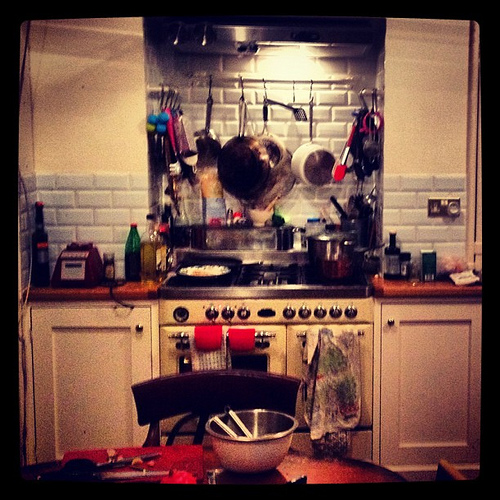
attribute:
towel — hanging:
[275, 344, 370, 421]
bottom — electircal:
[50, 242, 106, 284]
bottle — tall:
[32, 199, 50, 286]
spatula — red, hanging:
[334, 121, 351, 181]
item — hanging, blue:
[149, 100, 158, 121]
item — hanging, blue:
[156, 108, 168, 121]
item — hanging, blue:
[155, 126, 167, 136]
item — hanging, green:
[147, 127, 157, 139]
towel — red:
[229, 326, 254, 352]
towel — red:
[189, 325, 222, 350]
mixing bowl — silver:
[206, 408, 298, 471]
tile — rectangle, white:
[59, 171, 96, 189]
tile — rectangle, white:
[96, 174, 128, 187]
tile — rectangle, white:
[38, 190, 78, 207]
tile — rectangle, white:
[74, 189, 114, 206]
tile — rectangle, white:
[116, 190, 146, 206]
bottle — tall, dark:
[32, 201, 52, 283]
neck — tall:
[30, 205, 45, 231]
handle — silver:
[386, 318, 395, 328]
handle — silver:
[133, 325, 146, 333]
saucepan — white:
[296, 99, 336, 186]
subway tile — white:
[382, 192, 419, 208]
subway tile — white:
[418, 190, 466, 207]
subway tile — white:
[432, 172, 468, 190]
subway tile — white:
[398, 173, 434, 189]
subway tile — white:
[381, 173, 398, 190]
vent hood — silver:
[147, 19, 376, 62]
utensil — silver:
[229, 408, 252, 439]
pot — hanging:
[196, 97, 221, 163]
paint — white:
[403, 333, 466, 433]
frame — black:
[463, 30, 498, 456]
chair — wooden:
[126, 362, 306, 443]